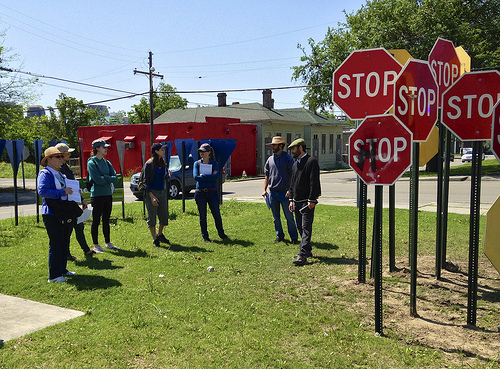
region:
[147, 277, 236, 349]
green grass in a field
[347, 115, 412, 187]
a stop sign with an h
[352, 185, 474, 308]
stop sign posts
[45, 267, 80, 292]
a womans feet in shoes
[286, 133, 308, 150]
a mans green hat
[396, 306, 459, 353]
brown dirt under signs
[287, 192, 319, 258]
a mans hands and pants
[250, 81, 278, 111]
a buildings chimney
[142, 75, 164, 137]
an electrical line post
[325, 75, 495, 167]
multiple stop signs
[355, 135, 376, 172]
black graffiti on sign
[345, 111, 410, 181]
red and white stop sign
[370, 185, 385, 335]
green painted metal pole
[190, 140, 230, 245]
woman standing in grass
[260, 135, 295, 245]
man standing next to guy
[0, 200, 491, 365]
green grassy area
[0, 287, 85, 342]
gray concrete block in grass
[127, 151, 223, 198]
dark colored truck on street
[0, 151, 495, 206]
black asphalt street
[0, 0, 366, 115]
bright clear blue sky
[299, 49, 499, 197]
There are many stop signs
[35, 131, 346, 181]
The people have hats on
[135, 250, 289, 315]
The grass is green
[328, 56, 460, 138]
The signs are red and white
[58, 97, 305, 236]
The building in the back is red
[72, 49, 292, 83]
The sky is blue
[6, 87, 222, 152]
There are trees in the back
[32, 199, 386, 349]
The people are standing on the ground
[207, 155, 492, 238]
The road is in the back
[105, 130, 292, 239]
There is one car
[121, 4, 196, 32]
this is the sky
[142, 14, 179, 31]
the sky is blue in color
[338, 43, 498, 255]
these are the signposts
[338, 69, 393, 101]
the signpost indicates stop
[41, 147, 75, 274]
this is a man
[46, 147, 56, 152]
this is a hat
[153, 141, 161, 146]
this is a cap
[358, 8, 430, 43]
this is a tree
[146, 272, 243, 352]
this is a grass area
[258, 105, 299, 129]
this is a building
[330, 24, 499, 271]
a bunch of stop signs very close to each other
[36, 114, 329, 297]
people standing on the grass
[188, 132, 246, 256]
a woman holding some white paper against her chest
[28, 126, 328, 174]
seven people wearing hats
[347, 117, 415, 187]
a stop sign with a black graffiti on it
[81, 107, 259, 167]
a red painted building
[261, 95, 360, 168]
a yellow house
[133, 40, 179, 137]
a telephone pole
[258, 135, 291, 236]
a man wearing a blue shirt and blue jeans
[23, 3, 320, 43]
a blue sky without any clouds